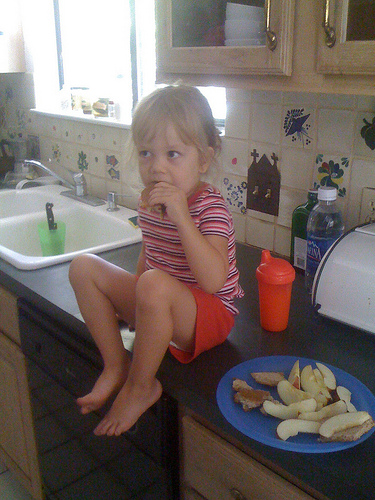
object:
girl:
[67, 84, 240, 441]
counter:
[2, 168, 375, 500]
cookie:
[135, 183, 169, 208]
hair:
[117, 79, 234, 170]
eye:
[138, 148, 152, 162]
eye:
[165, 148, 183, 162]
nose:
[150, 157, 168, 174]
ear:
[198, 145, 215, 176]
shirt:
[128, 180, 255, 315]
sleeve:
[197, 196, 234, 241]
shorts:
[167, 270, 239, 363]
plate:
[217, 351, 374, 455]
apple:
[267, 362, 368, 441]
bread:
[231, 365, 284, 414]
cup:
[244, 246, 302, 336]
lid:
[254, 247, 299, 289]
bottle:
[304, 180, 350, 310]